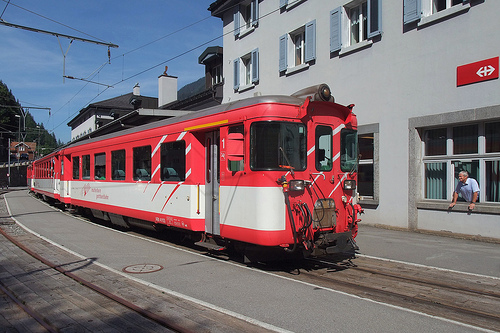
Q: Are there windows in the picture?
A: Yes, there is a window.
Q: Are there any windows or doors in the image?
A: Yes, there is a window.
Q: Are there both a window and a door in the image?
A: Yes, there are both a window and a door.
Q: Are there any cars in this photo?
A: No, there are no cars.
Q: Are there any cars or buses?
A: No, there are no cars or buses.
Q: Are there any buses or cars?
A: No, there are no cars or buses.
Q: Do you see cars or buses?
A: No, there are no cars or buses.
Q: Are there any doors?
A: Yes, there are doors.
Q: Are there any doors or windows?
A: Yes, there are doors.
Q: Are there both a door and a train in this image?
A: Yes, there are both a door and a train.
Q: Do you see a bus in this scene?
A: No, there are no buses.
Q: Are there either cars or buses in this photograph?
A: No, there are no buses or cars.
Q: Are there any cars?
A: No, there are no cars.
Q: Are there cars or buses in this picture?
A: No, there are no cars or buses.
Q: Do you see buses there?
A: No, there are no buses.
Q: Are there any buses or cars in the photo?
A: No, there are no buses or cars.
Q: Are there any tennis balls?
A: No, there are no tennis balls.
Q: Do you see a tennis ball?
A: No, there are no tennis balls.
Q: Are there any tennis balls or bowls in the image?
A: No, there are no tennis balls or bowls.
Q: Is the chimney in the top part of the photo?
A: Yes, the chimney is in the top of the image.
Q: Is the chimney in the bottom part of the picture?
A: No, the chimney is in the top of the image.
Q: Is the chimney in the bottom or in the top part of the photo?
A: The chimney is in the top of the image.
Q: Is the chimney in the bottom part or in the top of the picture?
A: The chimney is in the top of the image.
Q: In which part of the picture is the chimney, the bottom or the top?
A: The chimney is in the top of the image.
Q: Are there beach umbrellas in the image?
A: No, there are no beach umbrellas.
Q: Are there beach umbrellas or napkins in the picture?
A: No, there are no beach umbrellas or napkins.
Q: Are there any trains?
A: Yes, there is a train.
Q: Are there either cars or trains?
A: Yes, there is a train.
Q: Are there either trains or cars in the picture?
A: Yes, there is a train.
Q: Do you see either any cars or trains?
A: Yes, there is a train.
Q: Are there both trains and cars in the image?
A: No, there is a train but no cars.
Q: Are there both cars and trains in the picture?
A: No, there is a train but no cars.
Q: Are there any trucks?
A: No, there are no trucks.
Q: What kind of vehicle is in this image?
A: The vehicle is a train.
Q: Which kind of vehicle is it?
A: The vehicle is a train.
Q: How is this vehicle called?
A: This is a train.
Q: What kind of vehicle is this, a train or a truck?
A: This is a train.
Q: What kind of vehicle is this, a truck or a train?
A: This is a train.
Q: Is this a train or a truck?
A: This is a train.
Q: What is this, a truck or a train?
A: This is a train.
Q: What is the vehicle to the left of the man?
A: The vehicle is a train.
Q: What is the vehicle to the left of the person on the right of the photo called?
A: The vehicle is a train.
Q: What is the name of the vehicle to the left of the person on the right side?
A: The vehicle is a train.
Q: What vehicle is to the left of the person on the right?
A: The vehicle is a train.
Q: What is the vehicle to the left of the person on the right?
A: The vehicle is a train.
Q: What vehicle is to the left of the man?
A: The vehicle is a train.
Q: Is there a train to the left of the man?
A: Yes, there is a train to the left of the man.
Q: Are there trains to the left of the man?
A: Yes, there is a train to the left of the man.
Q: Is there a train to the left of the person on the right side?
A: Yes, there is a train to the left of the man.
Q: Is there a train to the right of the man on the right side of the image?
A: No, the train is to the left of the man.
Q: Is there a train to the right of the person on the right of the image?
A: No, the train is to the left of the man.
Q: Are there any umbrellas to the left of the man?
A: No, there is a train to the left of the man.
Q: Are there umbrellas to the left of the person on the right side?
A: No, there is a train to the left of the man.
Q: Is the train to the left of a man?
A: Yes, the train is to the left of a man.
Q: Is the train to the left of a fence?
A: No, the train is to the left of a man.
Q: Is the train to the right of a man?
A: No, the train is to the left of a man.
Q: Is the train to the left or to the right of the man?
A: The train is to the left of the man.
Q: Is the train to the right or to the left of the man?
A: The train is to the left of the man.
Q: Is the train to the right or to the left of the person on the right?
A: The train is to the left of the man.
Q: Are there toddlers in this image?
A: No, there are no toddlers.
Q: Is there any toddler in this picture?
A: No, there are no toddlers.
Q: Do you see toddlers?
A: No, there are no toddlers.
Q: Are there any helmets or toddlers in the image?
A: No, there are no toddlers or helmets.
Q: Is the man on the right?
A: Yes, the man is on the right of the image.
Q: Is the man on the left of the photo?
A: No, the man is on the right of the image.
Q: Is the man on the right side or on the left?
A: The man is on the right of the image.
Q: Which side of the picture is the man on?
A: The man is on the right of the image.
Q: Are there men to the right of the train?
A: Yes, there is a man to the right of the train.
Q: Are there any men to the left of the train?
A: No, the man is to the right of the train.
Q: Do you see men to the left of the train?
A: No, the man is to the right of the train.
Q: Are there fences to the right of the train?
A: No, there is a man to the right of the train.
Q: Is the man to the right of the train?
A: Yes, the man is to the right of the train.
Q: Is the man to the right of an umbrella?
A: No, the man is to the right of the train.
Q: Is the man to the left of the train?
A: No, the man is to the right of the train.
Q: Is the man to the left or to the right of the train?
A: The man is to the right of the train.